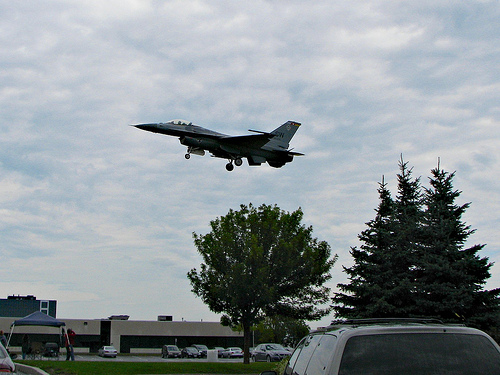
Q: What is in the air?
A: Plane.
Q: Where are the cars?
A: Parking lot.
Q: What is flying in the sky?
A: Fighter jet.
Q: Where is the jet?
A: In air.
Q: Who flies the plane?
A: Pilot.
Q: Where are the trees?
A: In grass.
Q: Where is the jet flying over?
A: Parking lot.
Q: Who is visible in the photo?
A: Man in red sweater.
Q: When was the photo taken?
A: Dull day.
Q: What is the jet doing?
A: Flying.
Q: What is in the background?
A: Buildings.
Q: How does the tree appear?
A: Green.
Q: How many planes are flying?
A: One.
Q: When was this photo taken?
A: During the daytime.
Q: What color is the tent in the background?
A: Blue.